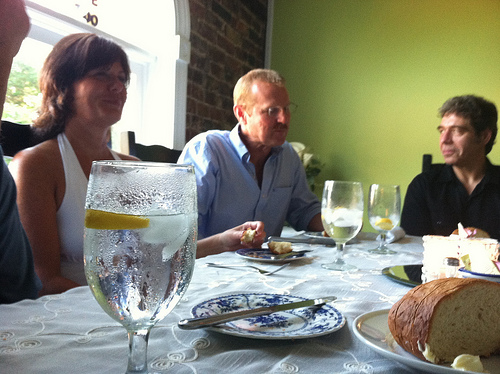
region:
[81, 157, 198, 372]
Glass with condensation drops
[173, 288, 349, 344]
A butter knife lying on a blue and white dish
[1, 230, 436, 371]
Nice white tablecloth with spiral design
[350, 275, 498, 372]
White plate with a loaf of fresh bread and some butter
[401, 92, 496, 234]
Man with curly dark hair wearing a black shirt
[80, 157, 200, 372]
Glass of water with ice and a slice of lemon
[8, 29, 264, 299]
Woman in a white halter holding a piece of bread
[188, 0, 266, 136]
Section of wall made with different color bricks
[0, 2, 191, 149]
Sun shining through a window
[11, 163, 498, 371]
Table with some bread and drinks on it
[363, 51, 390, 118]
This is a lime wall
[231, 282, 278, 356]
This small plate is very detailed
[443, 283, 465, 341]
There is bread here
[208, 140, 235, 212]
there is a denim shirt here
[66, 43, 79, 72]
This woman's hair is dark brown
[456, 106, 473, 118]
This man's hair is brown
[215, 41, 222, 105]
These bricks are red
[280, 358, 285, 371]
This is a white tablecloth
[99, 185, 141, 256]
There is a slice of lemon here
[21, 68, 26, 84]
There is an open window here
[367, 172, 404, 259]
The glass is clear.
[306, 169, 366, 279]
The glass is clear.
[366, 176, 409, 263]
The glass is almost empty.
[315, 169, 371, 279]
The glass is half full.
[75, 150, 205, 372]
The glass is clear.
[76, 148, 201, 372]
The glass is full.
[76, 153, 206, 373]
The glass has a wedge of lemon in it.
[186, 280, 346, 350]
The plate is round.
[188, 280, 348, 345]
The plate is blue and white.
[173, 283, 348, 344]
The plate has a knife on it.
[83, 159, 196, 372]
Condensation on a wine glass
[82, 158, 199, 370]
Wine glass filed with water, ice and a slice of lemon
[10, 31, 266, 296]
Brown haired woman in a white top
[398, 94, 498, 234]
Man in a black shirt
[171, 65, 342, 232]
Older man in a blue shirt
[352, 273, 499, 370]
Round white plate with bread and butter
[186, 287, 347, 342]
Butter knife resting on an empty plate with a blue design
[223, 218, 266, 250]
Hand holding a piece of bread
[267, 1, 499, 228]
Bright green wall behind the men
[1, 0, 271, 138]
Brick wall beside a window with white casing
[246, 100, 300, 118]
glasses on the man's face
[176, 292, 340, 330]
silver metal knife on the blue and white plate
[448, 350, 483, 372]
butter near the bread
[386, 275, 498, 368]
brown bread on the white plate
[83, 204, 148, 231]
lemon in the glass of water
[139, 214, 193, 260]
ice cubes in the glass of water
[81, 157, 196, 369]
clear glass of ice water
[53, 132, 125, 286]
woman wearing a white shirt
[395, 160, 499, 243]
black shirt on the man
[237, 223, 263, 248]
food in the woman's hand